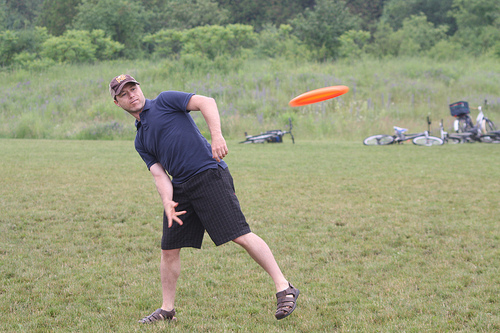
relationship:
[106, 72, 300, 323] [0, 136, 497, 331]
man on grass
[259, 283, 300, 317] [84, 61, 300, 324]
sandals on man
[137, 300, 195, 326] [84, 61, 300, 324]
sandals on man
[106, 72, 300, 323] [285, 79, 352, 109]
man throwing frisbee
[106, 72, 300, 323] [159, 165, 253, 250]
man wearing black shorts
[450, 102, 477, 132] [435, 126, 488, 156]
bicycle standing on grass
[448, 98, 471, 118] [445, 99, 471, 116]
blue box behind bike seat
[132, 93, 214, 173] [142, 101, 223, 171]
blue shirt on man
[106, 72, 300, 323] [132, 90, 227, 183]
man wearing blue shirt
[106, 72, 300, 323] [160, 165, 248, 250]
man wearing shorts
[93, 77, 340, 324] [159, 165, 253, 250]
man wearing black shorts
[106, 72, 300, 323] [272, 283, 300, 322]
man wearing sandals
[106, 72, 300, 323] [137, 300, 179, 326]
man wearing sandals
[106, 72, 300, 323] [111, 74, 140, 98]
man wearing hat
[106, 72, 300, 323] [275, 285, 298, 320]
man has foot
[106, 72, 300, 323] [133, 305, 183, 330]
man has foot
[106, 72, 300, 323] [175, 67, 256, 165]
man has hand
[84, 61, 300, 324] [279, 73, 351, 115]
man playing frisbee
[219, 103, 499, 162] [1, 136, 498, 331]
bicycles are beside field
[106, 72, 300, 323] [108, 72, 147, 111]
man has head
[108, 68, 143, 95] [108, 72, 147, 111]
cap on head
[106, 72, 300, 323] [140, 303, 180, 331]
man on foot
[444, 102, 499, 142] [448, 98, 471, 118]
bicycle with blue box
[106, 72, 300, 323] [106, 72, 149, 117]
man has head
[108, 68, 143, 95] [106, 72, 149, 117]
cap worn on head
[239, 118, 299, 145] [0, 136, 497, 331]
bicycles lying on grass